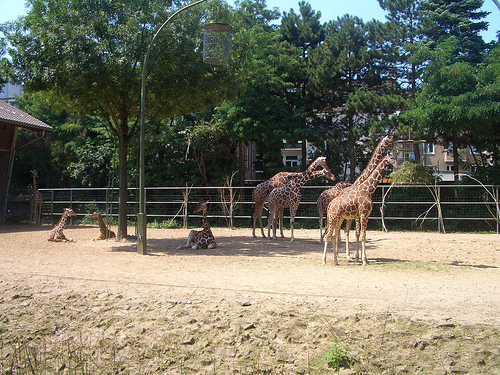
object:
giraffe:
[50, 207, 72, 242]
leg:
[61, 228, 78, 240]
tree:
[93, 7, 174, 242]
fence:
[34, 178, 496, 224]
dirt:
[258, 269, 271, 278]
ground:
[196, 277, 279, 319]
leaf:
[229, 56, 263, 91]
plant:
[200, 112, 237, 146]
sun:
[325, 11, 352, 21]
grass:
[148, 216, 190, 223]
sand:
[134, 274, 220, 289]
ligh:
[332, 5, 345, 12]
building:
[411, 122, 461, 166]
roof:
[1, 95, 52, 132]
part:
[169, 262, 248, 299]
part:
[213, 170, 243, 195]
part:
[350, 205, 368, 228]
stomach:
[330, 178, 368, 229]